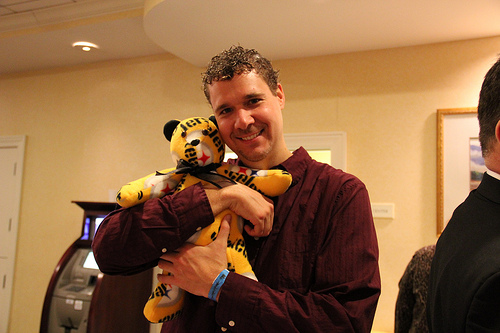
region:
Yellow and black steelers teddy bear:
[118, 114, 293, 324]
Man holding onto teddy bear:
[89, 44, 389, 331]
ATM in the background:
[34, 198, 123, 331]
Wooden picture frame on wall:
[434, 106, 485, 205]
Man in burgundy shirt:
[94, 51, 382, 330]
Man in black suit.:
[415, 46, 499, 331]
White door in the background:
[0, 131, 32, 332]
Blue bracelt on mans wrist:
[201, 266, 238, 298]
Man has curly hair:
[90, 36, 386, 332]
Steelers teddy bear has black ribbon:
[116, 113, 294, 331]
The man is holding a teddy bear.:
[136, 83, 256, 303]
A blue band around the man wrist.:
[204, 265, 229, 332]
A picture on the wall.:
[388, 83, 487, 225]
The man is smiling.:
[214, 118, 287, 163]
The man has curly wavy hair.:
[210, 55, 247, 78]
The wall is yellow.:
[61, 82, 153, 155]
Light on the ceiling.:
[69, 34, 102, 61]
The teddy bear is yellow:
[146, 113, 256, 293]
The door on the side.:
[5, 120, 35, 274]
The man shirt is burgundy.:
[261, 185, 378, 312]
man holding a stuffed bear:
[93, 45, 381, 330]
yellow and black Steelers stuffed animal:
[116, 112, 290, 320]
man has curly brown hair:
[200, 40, 287, 161]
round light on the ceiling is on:
[68, 37, 98, 52]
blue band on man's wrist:
[206, 267, 231, 303]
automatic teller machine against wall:
[35, 200, 122, 325]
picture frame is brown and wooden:
[434, 104, 474, 218]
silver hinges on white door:
[3, 130, 31, 331]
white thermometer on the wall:
[371, 198, 397, 219]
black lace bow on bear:
[156, 158, 236, 188]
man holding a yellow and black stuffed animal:
[90, 46, 381, 331]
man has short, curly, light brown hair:
[201, 46, 281, 107]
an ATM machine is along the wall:
[38, 196, 152, 331]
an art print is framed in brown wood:
[432, 106, 484, 236]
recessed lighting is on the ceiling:
[70, 39, 99, 53]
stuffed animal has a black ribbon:
[152, 156, 237, 191]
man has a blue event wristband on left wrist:
[206, 269, 231, 297]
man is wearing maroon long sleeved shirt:
[89, 145, 381, 331]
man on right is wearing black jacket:
[427, 60, 497, 332]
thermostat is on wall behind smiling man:
[369, 201, 399, 218]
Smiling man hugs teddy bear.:
[157, 42, 319, 302]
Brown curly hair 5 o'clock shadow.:
[211, 53, 289, 168]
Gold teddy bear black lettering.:
[139, 113, 286, 310]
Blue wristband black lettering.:
[194, 261, 239, 301]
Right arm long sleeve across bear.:
[82, 185, 297, 272]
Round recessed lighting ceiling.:
[42, 27, 149, 83]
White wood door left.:
[2, 121, 41, 329]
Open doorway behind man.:
[281, 128, 366, 170]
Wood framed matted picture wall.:
[422, 94, 483, 214]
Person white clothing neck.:
[472, 55, 499, 302]